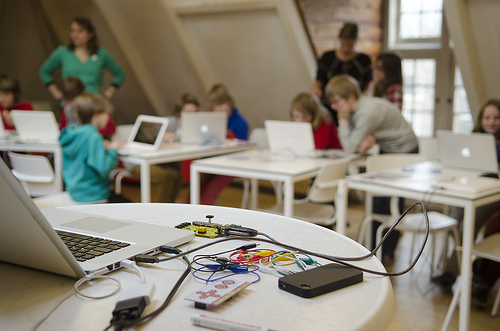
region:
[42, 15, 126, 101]
teacher in 3/4 length sleeve green t-shirt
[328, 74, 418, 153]
young boy in grey sweater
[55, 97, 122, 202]
young boy in blue sweatshirt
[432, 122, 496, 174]
white laptop with Apple symbol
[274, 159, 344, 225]
white wooden desk chair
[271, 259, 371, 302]
black rectangular electronic device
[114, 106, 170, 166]
white laptop with black screen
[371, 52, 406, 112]
young girl with brown hair and a plaid shirt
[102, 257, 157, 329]
black computer cable attached to white computer cable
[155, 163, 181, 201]
a child's leg in brown pants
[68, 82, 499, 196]
children sitting at tables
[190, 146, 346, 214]
legs on square white table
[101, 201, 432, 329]
wires on white table top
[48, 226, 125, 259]
black buttons on keyboard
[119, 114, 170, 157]
screen of open laptop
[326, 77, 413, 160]
bending boy with elbow on table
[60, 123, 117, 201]
blue shirt with hood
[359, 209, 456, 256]
seat of white table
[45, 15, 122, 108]
standing woman in green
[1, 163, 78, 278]
open cover of laptop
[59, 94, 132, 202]
Kid working on a computer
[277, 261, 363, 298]
Phone lying on a table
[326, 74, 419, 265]
Boy looking at computer screen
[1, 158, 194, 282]
Silver laptop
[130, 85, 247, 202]
Two people working together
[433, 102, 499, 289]
Girl working on a computer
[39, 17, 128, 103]
Woman observing room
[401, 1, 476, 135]
Window with light coming in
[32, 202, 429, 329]
Various wires for the computer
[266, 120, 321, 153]
White computer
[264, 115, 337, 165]
a large white laptop computer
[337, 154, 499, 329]
a white table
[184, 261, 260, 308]
a white and red controller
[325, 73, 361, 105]
a boy's short cut blonde hair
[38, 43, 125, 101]
a woman's long sleeve shirt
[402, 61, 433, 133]
part of a window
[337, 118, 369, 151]
the arm of a boy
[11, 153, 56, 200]
a white chair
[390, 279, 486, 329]
a section of brown hardwood floor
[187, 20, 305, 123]
part of a white wall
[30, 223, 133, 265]
laptop computer's black keyboard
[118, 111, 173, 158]
white laptop with black monitor face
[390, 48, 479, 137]
white french style stores with multi paned windows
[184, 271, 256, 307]
white remote with orange colored buttons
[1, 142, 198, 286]
silver laptop computer on white table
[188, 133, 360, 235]
white desk with white laptop on it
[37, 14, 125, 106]
dark haired woman with green shirt on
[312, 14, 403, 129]
dark haired woman helping female student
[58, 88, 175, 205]
child wearing green shirt working on computer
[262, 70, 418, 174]
male and female student working together on computer